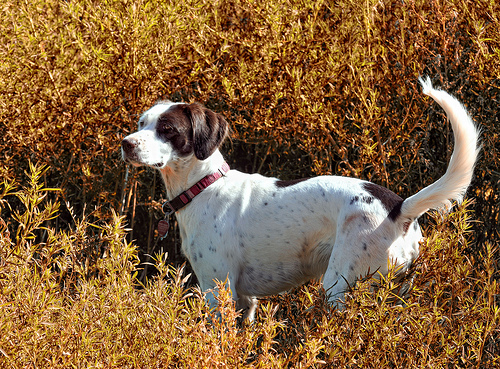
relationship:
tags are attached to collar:
[152, 195, 180, 227] [141, 164, 255, 224]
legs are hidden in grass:
[189, 251, 399, 316] [112, 268, 498, 366]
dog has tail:
[120, 75, 484, 369] [406, 52, 482, 193]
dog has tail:
[120, 75, 484, 369] [396, 70, 484, 224]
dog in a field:
[122, 90, 476, 369] [34, 269, 425, 369]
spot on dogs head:
[165, 102, 224, 150] [118, 104, 235, 228]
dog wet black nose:
[120, 75, 484, 369] [107, 126, 148, 195]